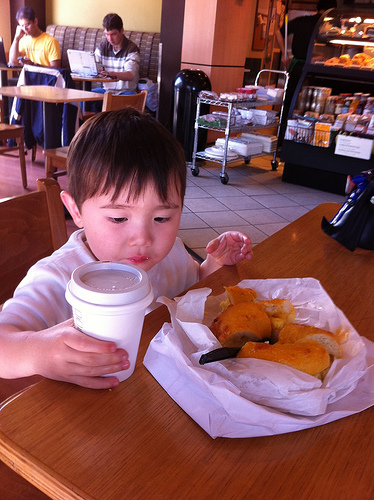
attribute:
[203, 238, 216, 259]
thumb — small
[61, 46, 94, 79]
rear of laptop — small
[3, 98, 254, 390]
child — small, asian, young, eating breakfast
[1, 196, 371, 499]
dining table — small, wooden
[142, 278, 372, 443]
food bag — crumpled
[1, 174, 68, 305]
chair — wooden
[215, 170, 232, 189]
cart wheel — black, small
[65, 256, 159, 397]
cup — white, large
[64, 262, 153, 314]
lid — white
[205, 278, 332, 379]
bread — large, delicious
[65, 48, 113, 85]
laptop — newer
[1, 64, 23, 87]
table — wooden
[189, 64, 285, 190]
cart — silver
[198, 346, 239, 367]
bread knife — black, used for cutting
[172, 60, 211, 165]
garbage bin — black, large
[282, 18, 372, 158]
refrigerated food — yummy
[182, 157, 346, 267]
floor tiles — grey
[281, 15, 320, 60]
shirt — black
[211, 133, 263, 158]
box — white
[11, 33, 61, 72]
shirt — yellow